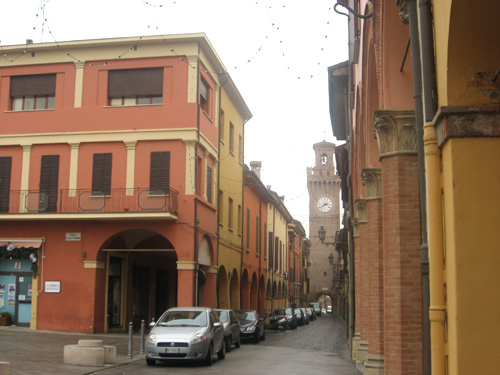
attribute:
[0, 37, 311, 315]
building — red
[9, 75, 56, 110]
window — large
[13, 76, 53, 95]
shade — half drawn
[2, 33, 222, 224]
trim — cream